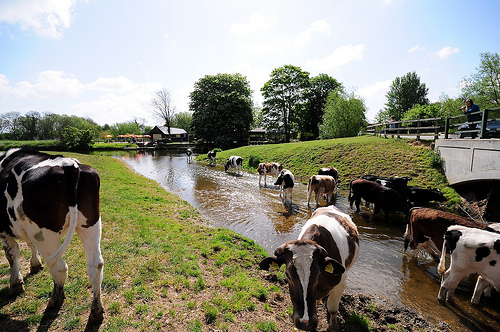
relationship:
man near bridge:
[460, 98, 479, 138] [433, 114, 498, 196]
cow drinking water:
[216, 152, 246, 176] [199, 170, 242, 214]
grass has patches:
[110, 241, 256, 327] [144, 235, 229, 318]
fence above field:
[373, 110, 498, 140] [336, 130, 412, 172]